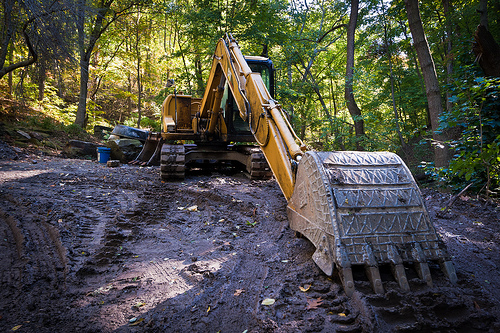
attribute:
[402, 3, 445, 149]
tree — skinny 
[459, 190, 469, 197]
leaf — fall colored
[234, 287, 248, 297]
leaf — fall colored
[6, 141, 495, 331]
ground — muddy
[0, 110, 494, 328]
ground — muddy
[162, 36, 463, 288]
bulldozer — yellow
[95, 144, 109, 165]
container — blue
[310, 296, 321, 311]
leaf — brown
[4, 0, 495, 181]
trees — green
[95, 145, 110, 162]
buck — blue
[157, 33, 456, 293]
backhoe — parked, yellow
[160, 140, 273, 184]
tracks — metal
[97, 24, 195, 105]
trees — shining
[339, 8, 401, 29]
sky — blue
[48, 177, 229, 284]
mud — tracked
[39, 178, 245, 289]
ground — muddy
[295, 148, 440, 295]
bucket — silver, dirty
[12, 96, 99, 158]
rocks — laying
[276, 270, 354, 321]
leaf — fall colored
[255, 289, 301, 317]
leaf — fall colored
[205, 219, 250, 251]
leaf — fall colored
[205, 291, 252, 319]
leaf — fall colored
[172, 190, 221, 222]
leaf — fall colored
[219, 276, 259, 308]
leaf — fall colored